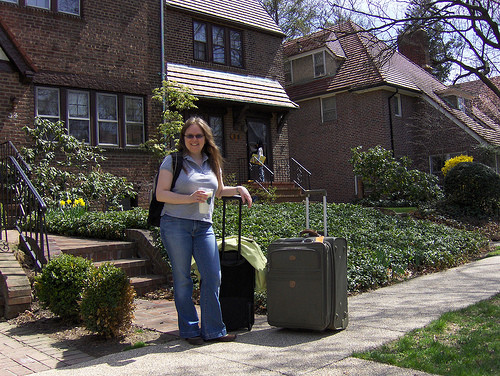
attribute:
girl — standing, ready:
[154, 114, 255, 345]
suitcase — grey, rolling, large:
[266, 185, 350, 332]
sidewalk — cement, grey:
[21, 253, 499, 374]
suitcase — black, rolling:
[217, 192, 258, 333]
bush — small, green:
[79, 261, 137, 341]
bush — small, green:
[32, 253, 89, 326]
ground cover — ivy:
[19, 199, 493, 317]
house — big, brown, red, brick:
[1, 1, 316, 210]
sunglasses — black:
[184, 132, 208, 139]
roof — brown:
[167, 0, 287, 38]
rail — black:
[0, 140, 51, 273]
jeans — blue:
[159, 213, 228, 341]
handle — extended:
[299, 185, 330, 236]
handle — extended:
[220, 194, 244, 259]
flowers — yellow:
[57, 199, 87, 208]